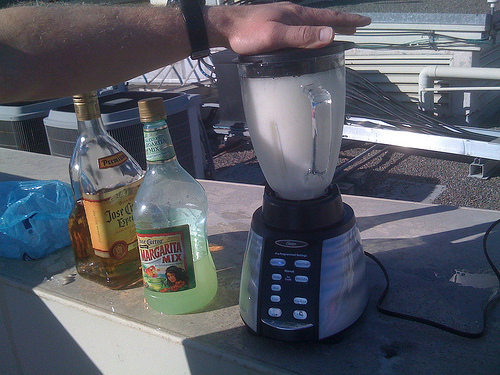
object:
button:
[294, 260, 311, 269]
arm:
[1, 0, 215, 104]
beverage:
[67, 184, 140, 290]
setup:
[0, 0, 500, 346]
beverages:
[237, 66, 348, 201]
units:
[40, 89, 207, 182]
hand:
[218, 0, 372, 56]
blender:
[230, 39, 355, 202]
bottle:
[66, 88, 145, 290]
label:
[134, 224, 197, 293]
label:
[81, 176, 144, 261]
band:
[180, 0, 212, 61]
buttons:
[259, 249, 322, 327]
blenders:
[230, 40, 372, 343]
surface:
[347, 343, 499, 370]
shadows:
[430, 246, 482, 265]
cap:
[137, 96, 167, 122]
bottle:
[131, 95, 219, 316]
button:
[269, 258, 286, 267]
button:
[271, 273, 283, 281]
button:
[271, 284, 283, 292]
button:
[269, 294, 282, 303]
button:
[293, 296, 308, 305]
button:
[267, 307, 283, 319]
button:
[291, 309, 307, 321]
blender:
[238, 182, 371, 345]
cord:
[364, 216, 499, 339]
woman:
[165, 265, 190, 292]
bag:
[0, 179, 77, 262]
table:
[0, 146, 500, 375]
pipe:
[417, 64, 500, 116]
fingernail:
[320, 27, 333, 42]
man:
[0, 0, 372, 98]